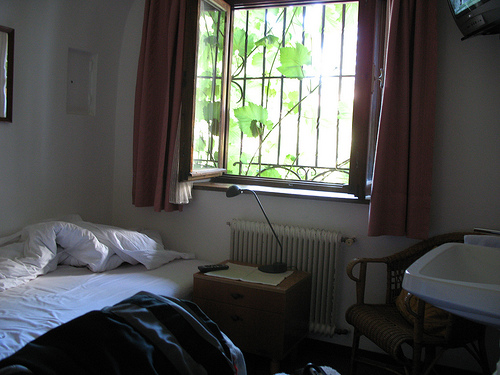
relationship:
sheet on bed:
[9, 219, 194, 363] [2, 220, 213, 354]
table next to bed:
[193, 249, 323, 361] [8, 220, 198, 372]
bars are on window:
[230, 3, 354, 185] [179, 1, 371, 205]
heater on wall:
[230, 222, 349, 306] [197, 197, 220, 255]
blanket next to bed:
[3, 292, 235, 373] [3, 214, 212, 346]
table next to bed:
[193, 249, 323, 361] [8, 222, 213, 368]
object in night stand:
[230, 179, 294, 276] [188, 273, 302, 365]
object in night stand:
[230, 179, 294, 276] [194, 249, 306, 359]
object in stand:
[230, 179, 294, 276] [186, 253, 306, 367]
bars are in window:
[230, 3, 354, 185] [179, 1, 371, 205]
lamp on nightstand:
[211, 176, 330, 313] [190, 262, 310, 371]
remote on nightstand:
[191, 250, 233, 275] [190, 262, 310, 371]